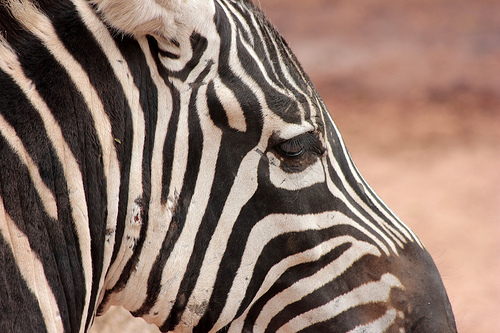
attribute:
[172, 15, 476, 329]
head — PROFILE, VIEW, ZEBRA'S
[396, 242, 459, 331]
nose — black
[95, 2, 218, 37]
ear — white, hairy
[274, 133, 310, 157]
eye — black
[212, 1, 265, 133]
stripe — black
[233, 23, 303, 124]
stripe — black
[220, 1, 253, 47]
stripe — black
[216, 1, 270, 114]
stripe — white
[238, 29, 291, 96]
stripe — white